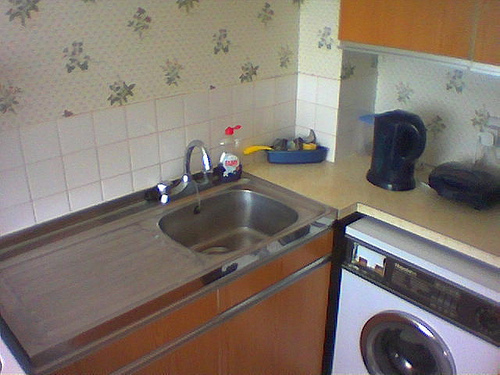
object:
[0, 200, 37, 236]
tile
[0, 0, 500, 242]
wall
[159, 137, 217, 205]
faucet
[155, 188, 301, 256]
sink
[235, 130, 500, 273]
yellow countertop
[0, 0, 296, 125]
wallpaper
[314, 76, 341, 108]
tile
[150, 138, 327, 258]
kitchen sink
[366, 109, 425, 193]
tea kettle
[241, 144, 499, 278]
counter top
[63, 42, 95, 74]
flower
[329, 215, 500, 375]
washing machine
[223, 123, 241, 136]
cap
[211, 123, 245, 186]
bottle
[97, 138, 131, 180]
tile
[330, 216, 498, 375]
dishwasher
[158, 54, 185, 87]
flower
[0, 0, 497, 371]
wooden cabinets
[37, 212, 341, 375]
drawers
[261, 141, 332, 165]
dish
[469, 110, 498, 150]
outlet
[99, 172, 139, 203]
tile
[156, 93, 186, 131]
tile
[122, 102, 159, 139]
tile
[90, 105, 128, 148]
tile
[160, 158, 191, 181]
tile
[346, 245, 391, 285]
panel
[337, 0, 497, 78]
cabinets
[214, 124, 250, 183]
detergent